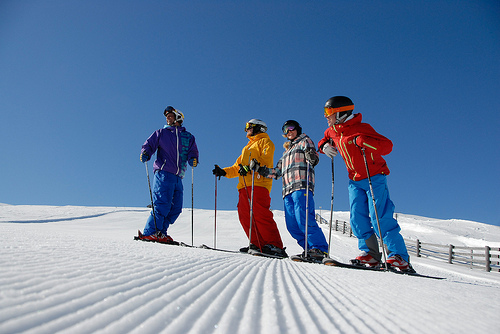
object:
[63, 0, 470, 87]
clouds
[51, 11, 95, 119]
sky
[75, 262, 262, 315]
hill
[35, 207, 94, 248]
snow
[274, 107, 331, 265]
skier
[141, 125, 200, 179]
jacket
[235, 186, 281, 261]
pats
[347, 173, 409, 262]
pants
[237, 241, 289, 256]
ski boots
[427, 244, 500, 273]
fence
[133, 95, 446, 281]
group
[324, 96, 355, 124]
helmet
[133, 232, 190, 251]
skis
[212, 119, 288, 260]
man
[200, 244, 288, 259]
skis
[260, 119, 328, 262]
man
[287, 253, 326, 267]
skis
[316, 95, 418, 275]
woman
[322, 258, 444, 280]
skis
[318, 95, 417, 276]
man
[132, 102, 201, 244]
man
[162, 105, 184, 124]
helmet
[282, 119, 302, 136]
helmet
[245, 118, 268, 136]
helmet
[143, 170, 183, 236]
pants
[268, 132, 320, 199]
coat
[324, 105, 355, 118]
goggles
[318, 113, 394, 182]
coat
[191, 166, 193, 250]
ski poles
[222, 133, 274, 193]
coat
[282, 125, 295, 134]
goggles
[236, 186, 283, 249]
pants